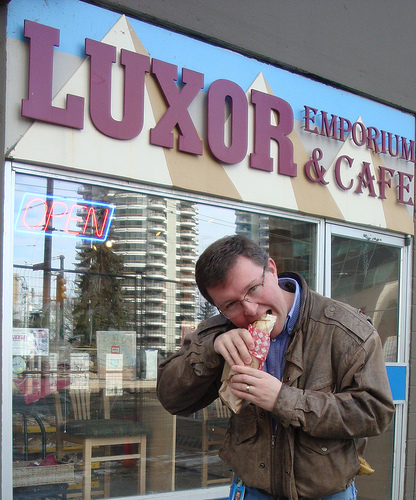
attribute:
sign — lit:
[21, 184, 119, 246]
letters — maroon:
[16, 23, 410, 228]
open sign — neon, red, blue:
[14, 192, 115, 243]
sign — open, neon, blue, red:
[13, 189, 115, 243]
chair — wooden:
[194, 424, 216, 457]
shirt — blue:
[147, 281, 410, 455]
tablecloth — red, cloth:
[17, 380, 71, 400]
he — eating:
[137, 232, 399, 432]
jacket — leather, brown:
[142, 268, 401, 465]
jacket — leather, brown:
[178, 295, 368, 482]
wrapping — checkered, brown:
[244, 325, 271, 368]